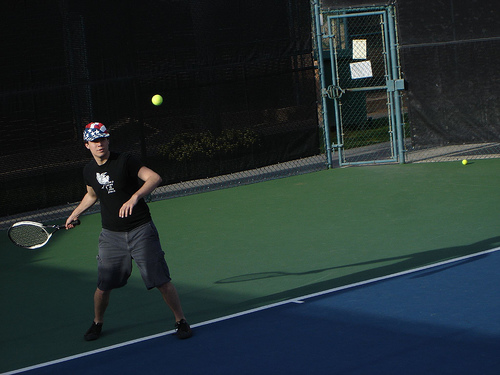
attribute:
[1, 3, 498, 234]
fence — chain link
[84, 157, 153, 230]
tee shirt — is black, is short-sleeved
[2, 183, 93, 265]
racquet — black, white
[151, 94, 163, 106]
ball — in mid air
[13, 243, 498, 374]
line — white line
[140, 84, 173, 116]
tennis ball — yellow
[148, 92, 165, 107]
tennis ball — green, in the air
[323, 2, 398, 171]
metal fence — is metal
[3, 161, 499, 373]
court — blue, is blue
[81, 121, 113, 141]
cap — American flag baseball cap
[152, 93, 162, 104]
tennis ball — is bright, is green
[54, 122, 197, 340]
man — playing tennis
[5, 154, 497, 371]
ground — is green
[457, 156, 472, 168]
tennis ball — yellow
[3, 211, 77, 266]
tennis racket — dark